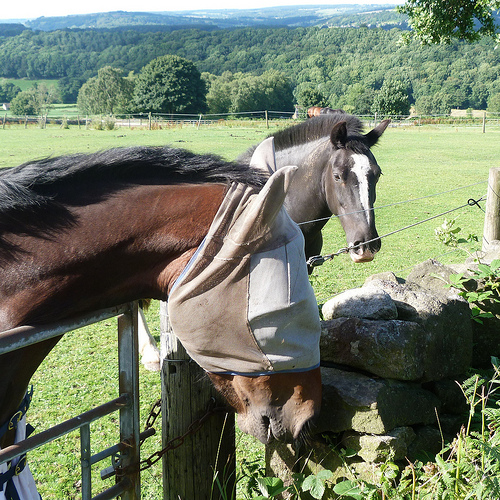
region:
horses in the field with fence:
[5, 77, 382, 482]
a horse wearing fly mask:
[16, 134, 337, 475]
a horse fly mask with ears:
[143, 128, 327, 429]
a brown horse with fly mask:
[13, 125, 333, 464]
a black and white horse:
[303, 101, 398, 258]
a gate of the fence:
[41, 294, 177, 499]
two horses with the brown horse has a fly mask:
[49, 108, 390, 473]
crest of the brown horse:
[21, 136, 161, 245]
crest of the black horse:
[278, 117, 322, 174]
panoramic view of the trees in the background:
[34, 18, 422, 92]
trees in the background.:
[0, 17, 499, 113]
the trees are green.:
[0, 16, 490, 116]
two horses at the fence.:
[0, 105, 405, 452]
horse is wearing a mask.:
[163, 135, 325, 387]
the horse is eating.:
[231, 385, 338, 459]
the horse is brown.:
[234, 108, 398, 269]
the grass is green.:
[373, 124, 498, 259]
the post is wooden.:
[477, 161, 499, 252]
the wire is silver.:
[301, 180, 488, 269]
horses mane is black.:
[0, 128, 276, 235]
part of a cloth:
[256, 292, 291, 341]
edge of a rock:
[348, 395, 367, 450]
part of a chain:
[146, 434, 170, 459]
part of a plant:
[442, 435, 487, 488]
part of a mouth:
[256, 405, 314, 452]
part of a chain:
[187, 405, 234, 443]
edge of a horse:
[251, 402, 285, 459]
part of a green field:
[63, 380, 95, 411]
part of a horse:
[256, 390, 291, 449]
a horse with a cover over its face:
[127, 147, 328, 469]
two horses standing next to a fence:
[101, 90, 405, 460]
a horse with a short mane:
[264, 105, 386, 215]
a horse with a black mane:
[36, 150, 232, 292]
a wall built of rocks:
[224, 218, 489, 497]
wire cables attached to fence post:
[295, 172, 497, 286]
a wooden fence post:
[480, 157, 498, 242]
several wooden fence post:
[51, 107, 278, 131]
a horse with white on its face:
[322, 137, 377, 257]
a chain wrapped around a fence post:
[89, 388, 227, 485]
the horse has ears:
[131, 42, 467, 257]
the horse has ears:
[243, 55, 417, 264]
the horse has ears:
[181, 56, 401, 348]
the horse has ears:
[217, 126, 425, 481]